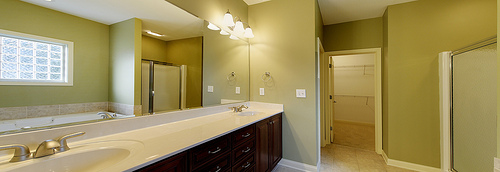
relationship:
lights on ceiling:
[205, 11, 253, 46] [4, 4, 500, 33]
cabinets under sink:
[140, 111, 301, 171] [0, 128, 141, 171]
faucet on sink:
[29, 138, 68, 160] [0, 128, 141, 171]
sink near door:
[224, 103, 253, 120] [322, 42, 382, 157]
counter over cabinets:
[1, 98, 281, 171] [140, 111, 301, 171]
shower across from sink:
[439, 43, 498, 172] [0, 128, 141, 171]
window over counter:
[3, 32, 80, 88] [1, 98, 281, 171]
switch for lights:
[292, 84, 309, 103] [205, 11, 253, 46]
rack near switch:
[262, 72, 279, 92] [292, 84, 309, 103]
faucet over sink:
[29, 138, 68, 160] [0, 128, 141, 171]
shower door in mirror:
[141, 58, 189, 112] [145, 54, 195, 113]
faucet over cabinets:
[29, 138, 68, 160] [140, 111, 301, 171]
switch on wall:
[292, 84, 309, 103] [252, 1, 312, 158]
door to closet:
[322, 42, 382, 157] [334, 43, 378, 152]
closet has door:
[334, 43, 378, 152] [322, 42, 382, 157]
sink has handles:
[0, 128, 141, 171] [3, 124, 86, 157]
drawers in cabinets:
[206, 129, 262, 170] [140, 111, 301, 171]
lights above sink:
[205, 11, 253, 46] [224, 103, 253, 120]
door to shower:
[322, 42, 382, 157] [439, 43, 498, 172]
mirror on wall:
[145, 54, 195, 113] [126, 28, 211, 119]